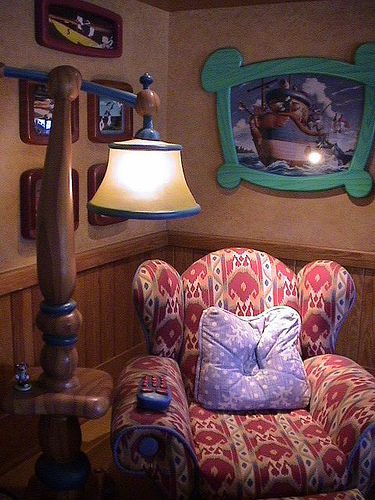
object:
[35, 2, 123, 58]
wooden frame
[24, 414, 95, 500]
base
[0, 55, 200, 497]
lamp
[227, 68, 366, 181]
boat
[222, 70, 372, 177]
picture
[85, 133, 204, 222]
lampshade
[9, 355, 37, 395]
figurine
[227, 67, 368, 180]
picture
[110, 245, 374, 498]
chair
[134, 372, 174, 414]
remote control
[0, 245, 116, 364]
paneling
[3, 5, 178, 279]
wall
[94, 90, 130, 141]
picture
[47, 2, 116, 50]
picture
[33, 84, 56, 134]
picture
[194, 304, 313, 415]
purple pillow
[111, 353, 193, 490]
chair arm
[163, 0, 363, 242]
wall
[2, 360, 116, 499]
table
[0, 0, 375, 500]
room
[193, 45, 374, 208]
aqua frame